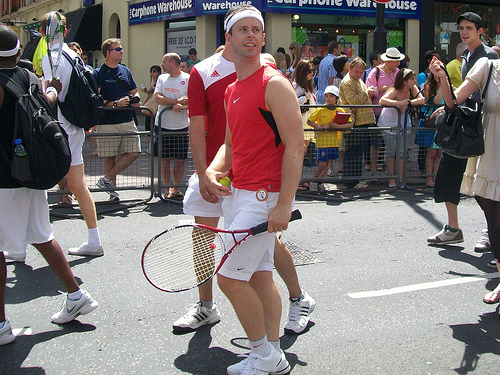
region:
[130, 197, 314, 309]
a tennis racket held by a player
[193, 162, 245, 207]
a tennis ball held by a player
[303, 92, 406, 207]
a barrier holding back a crowd.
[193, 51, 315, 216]
a red shirt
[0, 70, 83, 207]
a black backpack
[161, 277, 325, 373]
tennis shoes worn by players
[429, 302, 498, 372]
shadows on a street.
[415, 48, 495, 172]
a purse held by a woman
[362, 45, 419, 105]
a man in a pink shirt and had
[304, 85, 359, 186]
a boy in a yellow shirt.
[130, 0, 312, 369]
The player is holding a tennis racket.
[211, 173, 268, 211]
The player is holding a tennis ball.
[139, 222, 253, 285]
The tennis racket is black and red.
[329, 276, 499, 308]
There is a white stripe on the road.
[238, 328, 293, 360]
The player is wearing Nike socks.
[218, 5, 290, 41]
The player is wearing a sweatband.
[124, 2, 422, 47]
There is a building with a blue and white sign next to the building.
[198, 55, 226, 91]
The man behind the player is wearing an Adidas shirt.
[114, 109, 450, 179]
There is a gate keeping people back.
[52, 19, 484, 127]
There is a large crowd behind the gate.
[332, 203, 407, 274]
Road is grey color.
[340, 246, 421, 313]
White lines in the road.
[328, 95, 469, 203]
Rail is grey color.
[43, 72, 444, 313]
players are walking in the road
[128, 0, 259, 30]
board is blue color.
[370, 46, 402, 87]
man in pink dress is wearing the white hat.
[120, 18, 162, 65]
building is white color.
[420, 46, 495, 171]
Lady is carrying black color hand bag.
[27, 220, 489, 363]
Shadow is in road.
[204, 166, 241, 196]
Ball is green color.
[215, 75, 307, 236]
the shirt is red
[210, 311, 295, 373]
the shoes are white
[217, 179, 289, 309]
the shorts are white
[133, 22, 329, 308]
the man is holding a racket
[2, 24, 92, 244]
the backpack is black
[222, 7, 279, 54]
the headband is white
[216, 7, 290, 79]
the man is wearing a headband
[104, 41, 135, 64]
the man is wearing sunglasses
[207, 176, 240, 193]
the ball is yellow green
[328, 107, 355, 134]
the book is red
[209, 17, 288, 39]
White head band on man's head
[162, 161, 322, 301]
Men wearing white shorts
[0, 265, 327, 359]
People wearing white tennis shoes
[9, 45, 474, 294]
People walking in the road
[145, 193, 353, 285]
Man holding tennis racquet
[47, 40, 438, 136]
Many people on the side of the road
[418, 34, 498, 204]
Woman carrying large black bag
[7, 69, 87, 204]
Man with backpack on back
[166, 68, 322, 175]
Two men wearing red shirts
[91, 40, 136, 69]
Man wearing sunglasses